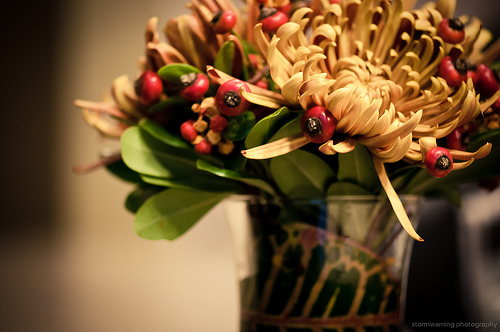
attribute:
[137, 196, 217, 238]
leaf — green 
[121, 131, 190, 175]
leaf — green 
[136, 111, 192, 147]
leaf — green 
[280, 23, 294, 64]
petal — tan 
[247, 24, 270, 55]
petal — tan 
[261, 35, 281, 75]
petal — tan 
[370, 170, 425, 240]
petal — flower 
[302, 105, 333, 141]
bud — red 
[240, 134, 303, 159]
petal — flower 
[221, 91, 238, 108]
end — black 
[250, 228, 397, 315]
detail — green 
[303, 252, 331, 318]
trim — tan 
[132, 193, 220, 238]
leaf — green 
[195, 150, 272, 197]
leaf — green 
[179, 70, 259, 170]
flowers — red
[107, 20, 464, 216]
flowers — clear view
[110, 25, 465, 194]
flowers — superb view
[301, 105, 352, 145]
berry — red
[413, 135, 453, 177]
berry — red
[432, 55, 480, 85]
berry — red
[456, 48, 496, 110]
berry — red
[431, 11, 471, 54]
berry — red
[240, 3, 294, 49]
berry — red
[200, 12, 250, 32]
berry — red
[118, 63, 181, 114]
berry — red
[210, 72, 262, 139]
part — red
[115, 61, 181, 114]
part — red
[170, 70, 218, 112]
part — red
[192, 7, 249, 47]
part — red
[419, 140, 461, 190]
part — red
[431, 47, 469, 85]
part — red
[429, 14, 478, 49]
part — red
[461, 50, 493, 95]
part — red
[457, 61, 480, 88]
part — red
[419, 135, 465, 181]
berry — red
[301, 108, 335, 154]
berry — red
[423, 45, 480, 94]
berry — red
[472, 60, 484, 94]
berry — red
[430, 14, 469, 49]
berry — red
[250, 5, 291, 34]
berry — red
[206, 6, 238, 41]
berry — red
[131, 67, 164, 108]
berry — red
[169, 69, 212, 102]
berry — red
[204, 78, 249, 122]
berry — red